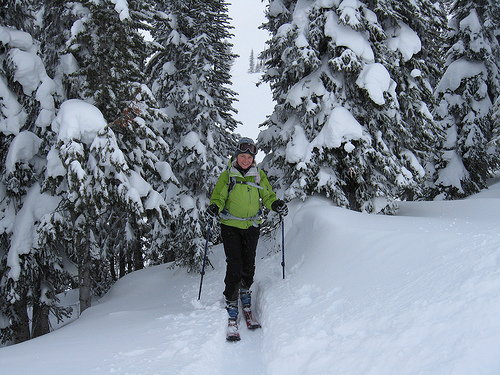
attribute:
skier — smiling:
[214, 141, 270, 322]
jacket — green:
[214, 151, 304, 223]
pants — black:
[218, 222, 263, 301]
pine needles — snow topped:
[386, 102, 431, 153]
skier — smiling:
[166, 116, 318, 329]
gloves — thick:
[263, 197, 290, 222]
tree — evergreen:
[243, 42, 260, 76]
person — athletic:
[208, 137, 288, 314]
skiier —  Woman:
[169, 125, 321, 360]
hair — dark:
[181, 126, 298, 341]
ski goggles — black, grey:
[234, 140, 259, 159]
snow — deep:
[316, 285, 433, 358]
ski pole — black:
[276, 210, 288, 279]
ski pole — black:
[195, 214, 219, 299]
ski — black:
[225, 301, 242, 341]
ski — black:
[241, 309, 261, 329]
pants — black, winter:
[222, 221, 259, 303]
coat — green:
[207, 166, 283, 232]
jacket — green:
[206, 169, 273, 231]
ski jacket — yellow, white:
[205, 162, 279, 230]